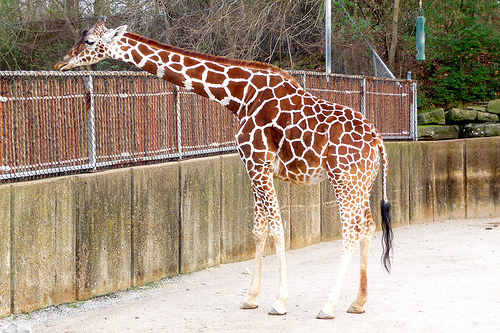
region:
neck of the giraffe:
[126, 29, 259, 106]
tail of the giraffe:
[363, 136, 434, 273]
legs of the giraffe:
[236, 201, 316, 294]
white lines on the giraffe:
[250, 94, 327, 158]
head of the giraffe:
[45, 16, 135, 88]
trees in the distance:
[443, 15, 490, 67]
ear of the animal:
[103, 22, 131, 52]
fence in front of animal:
[1, 32, 68, 133]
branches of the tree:
[211, 5, 298, 55]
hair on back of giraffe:
[133, 30, 311, 79]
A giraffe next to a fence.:
[21, 10, 391, 315]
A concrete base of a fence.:
[1, 139, 496, 309]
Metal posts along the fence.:
[0, 75, 416, 170]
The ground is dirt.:
[2, 216, 492, 331]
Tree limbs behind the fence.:
[140, 0, 313, 62]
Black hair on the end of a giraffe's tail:
[375, 202, 396, 274]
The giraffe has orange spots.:
[118, 35, 388, 315]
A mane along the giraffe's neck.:
[117, 31, 297, 77]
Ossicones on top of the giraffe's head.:
[82, 12, 107, 33]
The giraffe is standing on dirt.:
[239, 286, 367, 331]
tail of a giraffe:
[371, 122, 396, 262]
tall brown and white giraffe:
[85, 23, 406, 326]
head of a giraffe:
[38, 10, 143, 85]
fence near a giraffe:
[41, 85, 131, 157]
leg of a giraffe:
[261, 171, 297, 316]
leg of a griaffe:
[312, 182, 352, 318]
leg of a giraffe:
[235, 226, 266, 312]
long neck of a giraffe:
[140, 43, 236, 103]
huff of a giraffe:
[333, 295, 376, 322]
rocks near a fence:
[432, 102, 496, 138]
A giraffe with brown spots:
[51, 14, 403, 331]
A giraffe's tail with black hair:
[373, 137, 398, 282]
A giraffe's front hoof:
[265, 299, 287, 323]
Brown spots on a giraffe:
[253, 92, 301, 137]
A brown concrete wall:
[29, 186, 221, 281]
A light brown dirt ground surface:
[420, 264, 486, 321]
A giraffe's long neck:
[130, 25, 247, 115]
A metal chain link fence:
[13, 81, 163, 167]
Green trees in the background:
[438, 20, 493, 98]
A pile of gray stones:
[424, 105, 496, 136]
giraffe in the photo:
[14, 8, 412, 243]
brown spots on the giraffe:
[264, 100, 340, 162]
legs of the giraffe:
[213, 214, 310, 328]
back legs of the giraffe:
[308, 216, 391, 326]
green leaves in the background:
[436, 22, 488, 97]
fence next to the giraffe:
[17, 66, 144, 219]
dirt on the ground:
[411, 253, 473, 325]